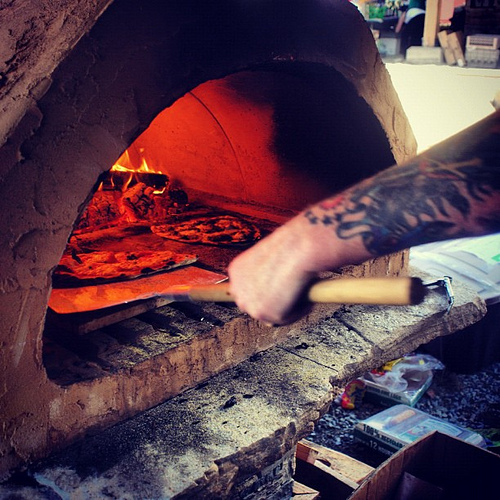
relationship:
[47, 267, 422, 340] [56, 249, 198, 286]
paddle getting pizza